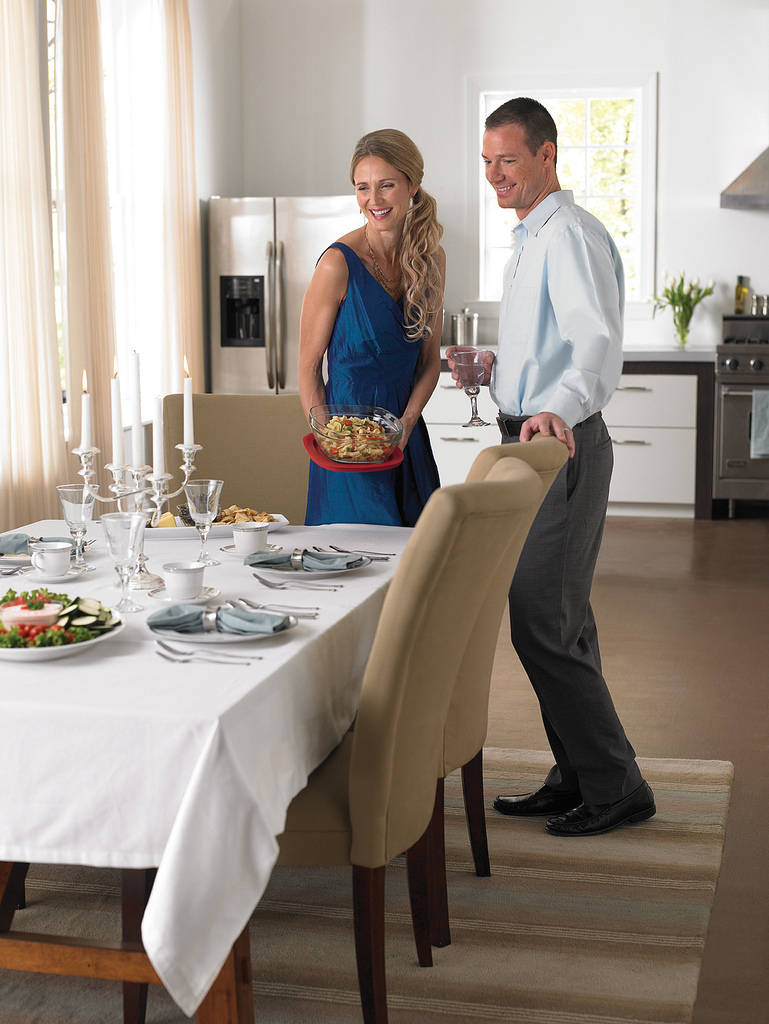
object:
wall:
[185, 0, 769, 350]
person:
[446, 95, 657, 835]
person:
[297, 129, 446, 526]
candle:
[79, 369, 91, 449]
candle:
[62, 402, 70, 443]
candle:
[151, 399, 164, 479]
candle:
[72, 375, 92, 454]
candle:
[183, 354, 194, 445]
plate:
[247, 550, 371, 580]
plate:
[0, 602, 127, 660]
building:
[0, 0, 769, 1024]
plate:
[147, 603, 298, 642]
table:
[0, 521, 416, 1024]